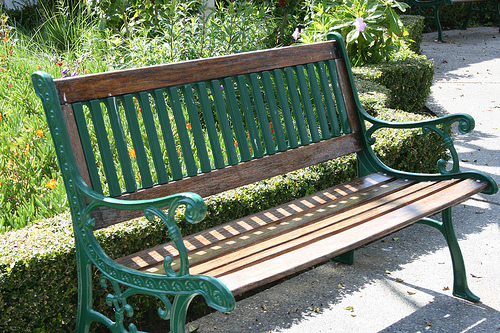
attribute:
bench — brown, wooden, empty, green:
[67, 34, 344, 288]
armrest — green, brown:
[86, 186, 171, 236]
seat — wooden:
[216, 173, 352, 253]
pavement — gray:
[341, 262, 490, 321]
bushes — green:
[19, 25, 182, 88]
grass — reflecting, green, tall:
[8, 156, 57, 217]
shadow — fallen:
[378, 256, 474, 329]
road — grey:
[443, 56, 497, 128]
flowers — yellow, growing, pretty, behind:
[264, 6, 359, 56]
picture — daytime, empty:
[20, 5, 480, 318]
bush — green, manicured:
[376, 59, 460, 117]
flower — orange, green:
[19, 130, 69, 185]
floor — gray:
[463, 223, 496, 259]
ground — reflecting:
[266, 291, 379, 324]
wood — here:
[144, 54, 249, 83]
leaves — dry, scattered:
[328, 287, 405, 333]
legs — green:
[100, 270, 189, 331]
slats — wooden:
[242, 192, 383, 291]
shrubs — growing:
[21, 157, 93, 288]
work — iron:
[47, 93, 102, 217]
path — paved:
[432, 17, 485, 94]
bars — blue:
[198, 94, 296, 119]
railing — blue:
[145, 186, 198, 213]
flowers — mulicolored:
[9, 122, 46, 163]